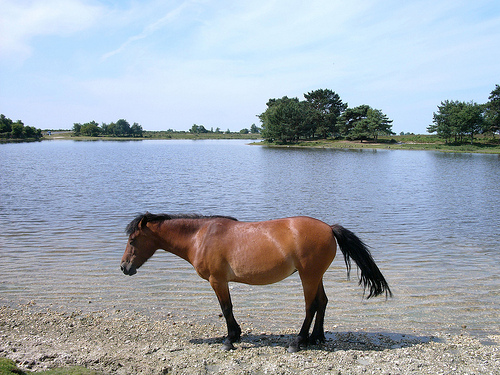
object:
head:
[117, 210, 172, 277]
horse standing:
[119, 207, 393, 355]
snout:
[116, 257, 142, 276]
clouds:
[0, 0, 500, 106]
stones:
[0, 302, 498, 374]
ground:
[0, 302, 498, 375]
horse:
[119, 209, 395, 353]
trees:
[248, 122, 261, 135]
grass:
[149, 131, 259, 141]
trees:
[253, 96, 325, 147]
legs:
[293, 263, 326, 337]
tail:
[327, 222, 393, 301]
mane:
[135, 209, 239, 223]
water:
[0, 138, 499, 348]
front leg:
[208, 282, 240, 342]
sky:
[0, 0, 498, 136]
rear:
[289, 215, 344, 281]